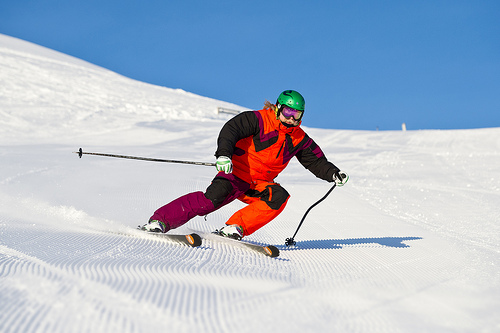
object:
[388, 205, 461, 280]
snow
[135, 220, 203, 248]
ski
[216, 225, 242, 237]
foot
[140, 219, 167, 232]
foot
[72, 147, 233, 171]
pole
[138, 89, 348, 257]
man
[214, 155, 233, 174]
right hand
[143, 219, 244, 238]
shoes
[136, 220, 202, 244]
ski boots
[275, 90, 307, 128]
head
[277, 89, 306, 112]
helmet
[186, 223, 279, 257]
left ski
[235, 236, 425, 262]
shadow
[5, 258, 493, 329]
snow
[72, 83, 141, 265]
outside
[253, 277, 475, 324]
outside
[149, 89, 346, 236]
suit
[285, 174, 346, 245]
pole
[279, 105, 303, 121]
goggles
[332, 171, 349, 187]
hand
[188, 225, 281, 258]
skis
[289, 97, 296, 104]
green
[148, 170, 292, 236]
pants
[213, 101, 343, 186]
ski jacket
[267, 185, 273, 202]
ski pants/zipper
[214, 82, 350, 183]
upper torso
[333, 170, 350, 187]
gloves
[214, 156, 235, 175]
gloves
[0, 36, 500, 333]
ski slope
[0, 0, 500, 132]
sky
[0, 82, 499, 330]
slope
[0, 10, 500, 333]
photo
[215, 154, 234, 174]
hand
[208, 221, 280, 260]
ski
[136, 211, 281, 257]
pair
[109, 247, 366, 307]
ground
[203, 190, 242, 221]
zipper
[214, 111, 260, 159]
sleeves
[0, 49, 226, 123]
hill